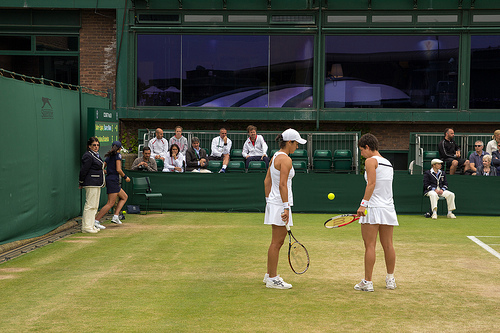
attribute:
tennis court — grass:
[0, 205, 496, 332]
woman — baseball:
[257, 126, 312, 299]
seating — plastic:
[131, 142, 499, 177]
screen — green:
[114, 162, 498, 214]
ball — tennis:
[323, 187, 353, 209]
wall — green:
[2, 74, 100, 228]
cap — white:
[280, 125, 310, 144]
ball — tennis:
[325, 191, 335, 199]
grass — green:
[419, 220, 456, 325]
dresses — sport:
[260, 195, 402, 229]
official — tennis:
[422, 157, 459, 222]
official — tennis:
[78, 136, 107, 238]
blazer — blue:
[419, 168, 449, 193]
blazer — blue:
[75, 149, 107, 188]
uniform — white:
[340, 132, 412, 234]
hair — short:
[359, 130, 381, 145]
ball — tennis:
[324, 190, 339, 204]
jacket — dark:
[82, 150, 110, 185]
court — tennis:
[6, 199, 498, 327]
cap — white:
[276, 126, 305, 148]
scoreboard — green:
[85, 106, 121, 143]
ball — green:
[326, 190, 338, 200]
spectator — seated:
[211, 122, 231, 175]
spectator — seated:
[133, 148, 158, 169]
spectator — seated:
[140, 128, 167, 172]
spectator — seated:
[240, 125, 268, 167]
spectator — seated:
[169, 126, 189, 155]